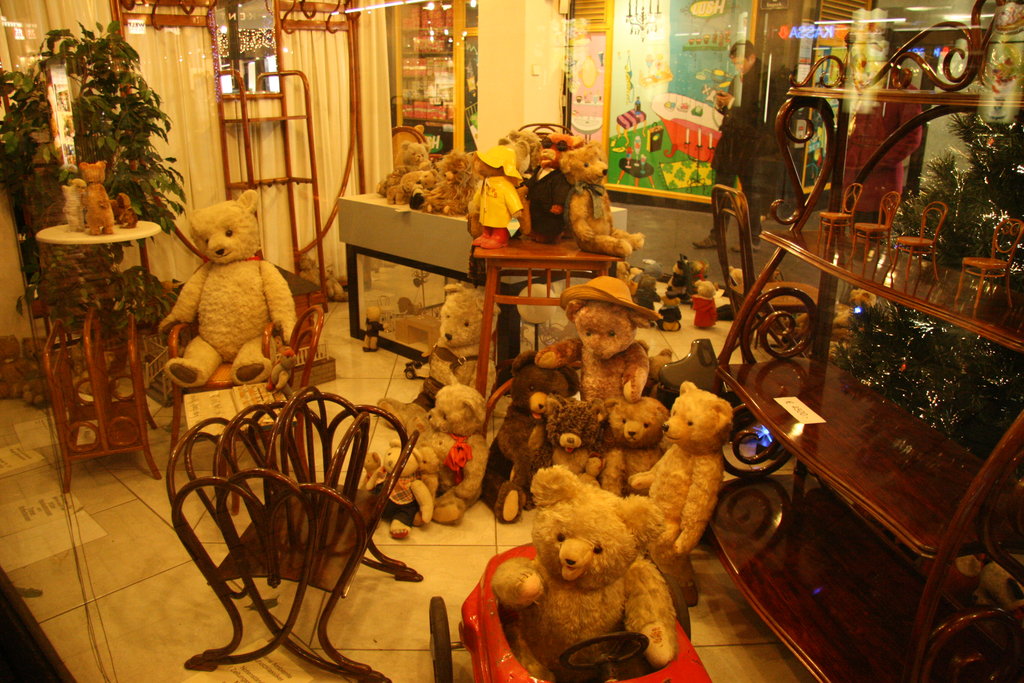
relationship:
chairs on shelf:
[723, 135, 963, 306] [764, 189, 987, 620]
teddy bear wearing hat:
[544, 305, 698, 452] [572, 273, 665, 341]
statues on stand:
[60, 148, 147, 229] [17, 212, 186, 480]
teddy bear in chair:
[183, 193, 270, 379] [172, 294, 363, 429]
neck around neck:
[443, 434, 471, 485] [427, 424, 490, 455]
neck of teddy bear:
[427, 424, 490, 455] [397, 398, 538, 526]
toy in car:
[490, 464, 676, 682] [405, 527, 728, 677]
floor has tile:
[27, 460, 188, 646] [51, 501, 170, 599]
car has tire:
[418, 529, 715, 679] [418, 584, 460, 678]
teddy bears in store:
[172, 119, 749, 673] [8, 4, 1018, 679]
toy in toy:
[490, 464, 676, 682] [490, 464, 676, 682]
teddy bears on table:
[468, 130, 644, 258] [468, 249, 626, 286]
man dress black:
[697, 26, 756, 251] [703, 102, 749, 211]